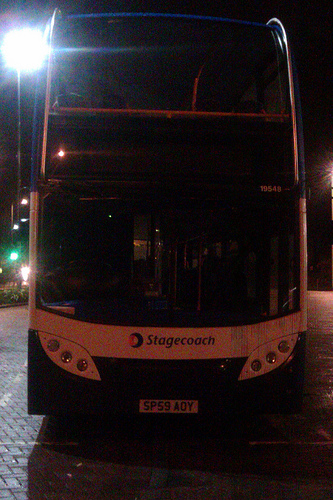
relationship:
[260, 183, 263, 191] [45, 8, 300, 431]
number on front of bus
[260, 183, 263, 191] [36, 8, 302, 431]
number on front of bus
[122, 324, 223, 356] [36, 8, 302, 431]
design on front of bus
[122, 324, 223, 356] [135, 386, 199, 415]
design above license plate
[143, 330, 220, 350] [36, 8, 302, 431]
word front of bus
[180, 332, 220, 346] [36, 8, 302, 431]
word on front of bus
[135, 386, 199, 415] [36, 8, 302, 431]
license plate on front of bus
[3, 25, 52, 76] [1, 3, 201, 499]
light on left side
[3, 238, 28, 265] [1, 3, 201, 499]
light on left side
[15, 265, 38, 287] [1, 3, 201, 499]
light on left side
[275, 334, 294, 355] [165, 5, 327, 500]
light on right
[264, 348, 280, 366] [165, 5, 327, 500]
light on right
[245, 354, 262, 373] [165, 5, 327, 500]
light on right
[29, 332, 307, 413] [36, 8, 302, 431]
paint on lower part of bus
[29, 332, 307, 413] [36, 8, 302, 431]
paint on front of bus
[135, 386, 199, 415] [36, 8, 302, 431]
plate on front of bus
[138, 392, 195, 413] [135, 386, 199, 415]
lettering on plate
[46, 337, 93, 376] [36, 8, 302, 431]
light on front of bus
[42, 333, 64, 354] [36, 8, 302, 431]
light on front of bus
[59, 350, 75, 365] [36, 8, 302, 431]
light on front of bus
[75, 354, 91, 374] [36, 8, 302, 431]
light on front of bus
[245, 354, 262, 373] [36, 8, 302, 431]
light on front of bus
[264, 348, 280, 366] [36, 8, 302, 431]
light on front of bus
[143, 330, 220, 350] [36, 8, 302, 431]
stagecoach on front of bus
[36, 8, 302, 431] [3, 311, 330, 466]
bus parked on ground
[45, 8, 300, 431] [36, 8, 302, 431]
front of bus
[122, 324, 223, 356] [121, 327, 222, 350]
bus company has logo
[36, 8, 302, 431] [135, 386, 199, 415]
bus has license plate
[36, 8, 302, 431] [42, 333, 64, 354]
bus has light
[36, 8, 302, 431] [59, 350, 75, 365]
bus has light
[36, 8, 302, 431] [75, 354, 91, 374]
bus has light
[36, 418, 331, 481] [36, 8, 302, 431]
shadow of bus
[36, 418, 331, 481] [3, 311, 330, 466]
shadow on bricks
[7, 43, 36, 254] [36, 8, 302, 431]
pole on bus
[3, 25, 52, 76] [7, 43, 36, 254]
light on pole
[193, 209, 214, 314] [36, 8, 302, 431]
pole inside bus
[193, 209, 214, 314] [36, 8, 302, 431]
pole on bus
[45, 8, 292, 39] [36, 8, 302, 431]
roof on bus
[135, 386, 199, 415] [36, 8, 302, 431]
number plate of bus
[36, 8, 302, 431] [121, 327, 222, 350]
bus has name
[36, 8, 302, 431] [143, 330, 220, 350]
bus has writings